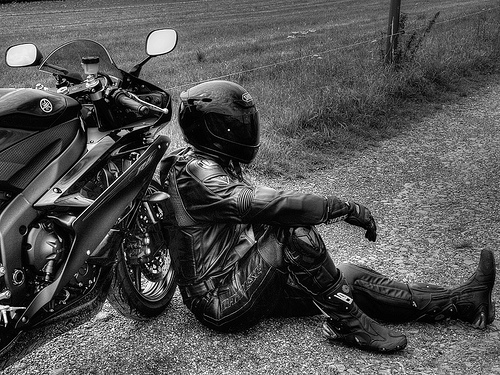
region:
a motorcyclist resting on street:
[161, 81, 498, 352]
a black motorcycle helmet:
[173, 78, 261, 166]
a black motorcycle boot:
[403, 247, 494, 332]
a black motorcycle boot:
[302, 270, 402, 355]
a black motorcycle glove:
[323, 194, 380, 245]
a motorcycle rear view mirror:
[146, 27, 176, 57]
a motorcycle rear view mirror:
[4, 42, 38, 69]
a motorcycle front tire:
[107, 176, 177, 326]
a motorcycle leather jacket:
[159, 147, 334, 297]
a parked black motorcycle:
[0, 26, 177, 366]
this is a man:
[183, 87, 379, 372]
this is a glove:
[355, 198, 385, 225]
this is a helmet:
[174, 90, 242, 117]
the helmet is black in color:
[201, 86, 236, 107]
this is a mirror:
[148, 25, 178, 47]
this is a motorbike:
[17, 40, 114, 311]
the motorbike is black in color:
[93, 198, 116, 227]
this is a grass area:
[276, 27, 325, 115]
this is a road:
[404, 131, 464, 181]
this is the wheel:
[114, 275, 160, 317]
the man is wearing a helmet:
[179, 79, 260, 166]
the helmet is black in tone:
[177, 80, 261, 167]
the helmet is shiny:
[176, 76, 262, 162]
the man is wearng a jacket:
[160, 145, 325, 320]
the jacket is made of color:
[156, 145, 341, 325]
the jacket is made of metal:
[161, 145, 331, 323]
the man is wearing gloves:
[325, 194, 384, 242]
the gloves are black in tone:
[325, 190, 380, 243]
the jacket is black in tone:
[160, 144, 265, 293]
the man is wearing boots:
[310, 270, 408, 356]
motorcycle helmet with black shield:
[167, 71, 274, 171]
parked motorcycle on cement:
[0, 28, 194, 345]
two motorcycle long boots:
[311, 246, 493, 356]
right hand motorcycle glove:
[311, 180, 387, 245]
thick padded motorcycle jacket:
[160, 150, 330, 312]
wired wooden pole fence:
[344, 6, 428, 68]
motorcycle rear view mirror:
[139, 19, 196, 64]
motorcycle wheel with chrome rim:
[91, 173, 185, 316]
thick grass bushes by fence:
[306, 69, 381, 126]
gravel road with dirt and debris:
[410, 155, 485, 225]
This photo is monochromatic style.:
[24, 32, 463, 352]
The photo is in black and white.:
[77, 18, 425, 263]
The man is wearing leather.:
[171, 144, 365, 311]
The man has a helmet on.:
[178, 84, 260, 156]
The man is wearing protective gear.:
[173, 160, 486, 349]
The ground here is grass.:
[278, 64, 448, 140]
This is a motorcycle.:
[2, 55, 174, 320]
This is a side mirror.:
[121, 17, 208, 82]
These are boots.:
[308, 269, 495, 355]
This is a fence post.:
[377, 0, 421, 80]